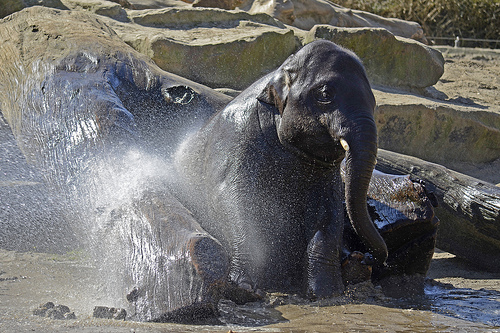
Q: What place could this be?
A: It is a zoo.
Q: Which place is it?
A: It is a zoo.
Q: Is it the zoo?
A: Yes, it is the zoo.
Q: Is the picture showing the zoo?
A: Yes, it is showing the zoo.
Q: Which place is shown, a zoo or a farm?
A: It is a zoo.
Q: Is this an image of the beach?
A: No, the picture is showing the zoo.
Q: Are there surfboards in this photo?
A: No, there are no surfboards.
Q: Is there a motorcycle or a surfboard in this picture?
A: No, there are no surfboards or motorcycles.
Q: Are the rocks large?
A: Yes, the rocks are large.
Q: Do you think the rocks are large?
A: Yes, the rocks are large.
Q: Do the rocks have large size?
A: Yes, the rocks are large.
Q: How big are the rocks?
A: The rocks are large.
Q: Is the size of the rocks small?
A: No, the rocks are large.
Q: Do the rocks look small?
A: No, the rocks are large.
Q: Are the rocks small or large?
A: The rocks are large.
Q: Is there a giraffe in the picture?
A: No, there are no giraffes.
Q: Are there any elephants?
A: Yes, there is an elephant.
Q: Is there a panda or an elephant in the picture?
A: Yes, there is an elephant.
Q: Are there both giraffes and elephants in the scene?
A: No, there is an elephant but no giraffes.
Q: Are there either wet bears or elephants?
A: Yes, there is a wet elephant.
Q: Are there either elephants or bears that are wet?
A: Yes, the elephant is wet.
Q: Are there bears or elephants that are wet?
A: Yes, the elephant is wet.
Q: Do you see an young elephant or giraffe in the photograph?
A: Yes, there is a young elephant.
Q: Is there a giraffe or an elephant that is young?
A: Yes, the elephant is young.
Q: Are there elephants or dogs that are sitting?
A: Yes, the elephant is sitting.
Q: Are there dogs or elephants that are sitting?
A: Yes, the elephant is sitting.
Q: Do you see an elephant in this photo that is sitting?
A: Yes, there is an elephant that is sitting.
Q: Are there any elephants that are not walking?
A: Yes, there is an elephant that is sitting.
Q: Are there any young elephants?
A: Yes, there is a young elephant.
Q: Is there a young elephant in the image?
A: Yes, there is a young elephant.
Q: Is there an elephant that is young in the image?
A: Yes, there is a young elephant.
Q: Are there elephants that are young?
A: Yes, there is an elephant that is young.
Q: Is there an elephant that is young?
A: Yes, there is an elephant that is young.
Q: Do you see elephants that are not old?
A: Yes, there is an young elephant.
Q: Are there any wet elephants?
A: Yes, there is a wet elephant.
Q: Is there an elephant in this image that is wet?
A: Yes, there is an elephant that is wet.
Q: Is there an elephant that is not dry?
A: Yes, there is a wet elephant.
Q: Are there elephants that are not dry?
A: Yes, there is a wet elephant.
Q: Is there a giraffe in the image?
A: No, there are no giraffes.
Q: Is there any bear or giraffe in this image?
A: No, there are no giraffes or bears.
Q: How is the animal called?
A: The animal is an elephant.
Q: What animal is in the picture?
A: The animal is an elephant.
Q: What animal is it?
A: The animal is an elephant.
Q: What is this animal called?
A: That is an elephant.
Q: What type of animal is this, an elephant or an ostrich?
A: That is an elephant.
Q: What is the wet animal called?
A: The animal is an elephant.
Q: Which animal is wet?
A: The animal is an elephant.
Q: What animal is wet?
A: The animal is an elephant.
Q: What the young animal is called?
A: The animal is an elephant.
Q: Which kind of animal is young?
A: The animal is an elephant.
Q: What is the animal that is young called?
A: The animal is an elephant.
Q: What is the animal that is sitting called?
A: The animal is an elephant.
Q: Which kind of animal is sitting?
A: The animal is an elephant.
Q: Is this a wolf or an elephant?
A: This is an elephant.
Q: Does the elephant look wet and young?
A: Yes, the elephant is wet and young.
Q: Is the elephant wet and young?
A: Yes, the elephant is wet and young.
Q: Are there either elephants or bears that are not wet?
A: No, there is an elephant but it is wet.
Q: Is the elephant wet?
A: Yes, the elephant is wet.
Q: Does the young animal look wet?
A: Yes, the elephant is wet.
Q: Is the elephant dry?
A: No, the elephant is wet.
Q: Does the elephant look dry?
A: No, the elephant is wet.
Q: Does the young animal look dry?
A: No, the elephant is wet.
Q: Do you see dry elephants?
A: No, there is an elephant but it is wet.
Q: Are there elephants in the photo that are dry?
A: No, there is an elephant but it is wet.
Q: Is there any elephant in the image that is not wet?
A: No, there is an elephant but it is wet.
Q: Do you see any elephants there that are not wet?
A: No, there is an elephant but it is wet.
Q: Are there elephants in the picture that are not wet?
A: No, there is an elephant but it is wet.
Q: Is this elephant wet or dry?
A: The elephant is wet.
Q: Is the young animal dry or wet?
A: The elephant is wet.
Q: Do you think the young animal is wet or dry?
A: The elephant is wet.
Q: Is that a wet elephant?
A: Yes, that is a wet elephant.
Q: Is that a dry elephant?
A: No, that is a wet elephant.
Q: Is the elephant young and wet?
A: Yes, the elephant is young and wet.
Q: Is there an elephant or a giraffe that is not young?
A: No, there is an elephant but it is young.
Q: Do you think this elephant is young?
A: Yes, the elephant is young.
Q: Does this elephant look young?
A: Yes, the elephant is young.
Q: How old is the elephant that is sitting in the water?
A: The elephant is young.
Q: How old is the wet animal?
A: The elephant is young.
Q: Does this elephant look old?
A: No, the elephant is young.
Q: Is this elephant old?
A: No, the elephant is young.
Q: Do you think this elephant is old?
A: No, the elephant is young.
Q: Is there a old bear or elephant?
A: No, there is an elephant but it is young.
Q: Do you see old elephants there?
A: No, there is an elephant but it is young.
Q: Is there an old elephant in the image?
A: No, there is an elephant but it is young.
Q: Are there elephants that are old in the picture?
A: No, there is an elephant but it is young.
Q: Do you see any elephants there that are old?
A: No, there is an elephant but it is young.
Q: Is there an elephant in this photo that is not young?
A: No, there is an elephant but it is young.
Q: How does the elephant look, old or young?
A: The elephant is young.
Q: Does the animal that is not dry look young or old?
A: The elephant is young.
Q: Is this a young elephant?
A: Yes, this is a young elephant.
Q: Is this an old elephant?
A: No, this is a young elephant.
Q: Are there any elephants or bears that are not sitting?
A: No, there is an elephant but it is sitting.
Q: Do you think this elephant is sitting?
A: Yes, the elephant is sitting.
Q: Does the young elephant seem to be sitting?
A: Yes, the elephant is sitting.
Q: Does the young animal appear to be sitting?
A: Yes, the elephant is sitting.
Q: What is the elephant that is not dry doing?
A: The elephant is sitting.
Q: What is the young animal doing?
A: The elephant is sitting.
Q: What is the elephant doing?
A: The elephant is sitting.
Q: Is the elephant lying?
A: No, the elephant is sitting.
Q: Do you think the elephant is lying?
A: No, the elephant is sitting.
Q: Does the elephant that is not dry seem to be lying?
A: No, the elephant is sitting.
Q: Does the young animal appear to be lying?
A: No, the elephant is sitting.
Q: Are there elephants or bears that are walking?
A: No, there is an elephant but it is sitting.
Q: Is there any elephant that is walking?
A: No, there is an elephant but it is sitting.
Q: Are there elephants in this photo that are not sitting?
A: No, there is an elephant but it is sitting.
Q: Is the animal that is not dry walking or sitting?
A: The elephant is sitting.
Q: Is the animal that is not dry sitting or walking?
A: The elephant is sitting.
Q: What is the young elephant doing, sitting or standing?
A: The elephant is sitting.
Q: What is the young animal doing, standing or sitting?
A: The elephant is sitting.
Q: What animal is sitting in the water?
A: The elephant is sitting in the water.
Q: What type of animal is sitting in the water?
A: The animal is an elephant.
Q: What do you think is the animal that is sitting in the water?
A: The animal is an elephant.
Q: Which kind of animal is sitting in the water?
A: The animal is an elephant.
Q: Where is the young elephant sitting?
A: The elephant is sitting in the water.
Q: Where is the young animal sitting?
A: The elephant is sitting in the water.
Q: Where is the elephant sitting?
A: The elephant is sitting in the water.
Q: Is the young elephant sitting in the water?
A: Yes, the elephant is sitting in the water.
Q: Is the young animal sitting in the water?
A: Yes, the elephant is sitting in the water.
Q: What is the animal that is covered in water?
A: The animal is an elephant.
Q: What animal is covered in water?
A: The animal is an elephant.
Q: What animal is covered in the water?
A: The animal is an elephant.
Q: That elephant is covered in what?
A: The elephant is covered in water.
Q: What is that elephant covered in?
A: The elephant is covered in water.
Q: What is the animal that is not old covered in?
A: The elephant is covered in water.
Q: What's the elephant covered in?
A: The elephant is covered in water.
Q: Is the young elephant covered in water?
A: Yes, the elephant is covered in water.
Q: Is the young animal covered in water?
A: Yes, the elephant is covered in water.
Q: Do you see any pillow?
A: No, there are no pillows.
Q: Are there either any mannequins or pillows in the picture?
A: No, there are no pillows or mannequins.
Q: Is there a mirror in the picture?
A: No, there are no mirrors.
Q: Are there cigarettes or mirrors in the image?
A: No, there are no mirrors or cigarettes.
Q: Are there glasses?
A: No, there are no glasses.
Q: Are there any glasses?
A: No, there are no glasses.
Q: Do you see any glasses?
A: No, there are no glasses.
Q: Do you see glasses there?
A: No, there are no glasses.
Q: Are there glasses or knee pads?
A: No, there are no glasses or knee pads.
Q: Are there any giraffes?
A: No, there are no giraffes.